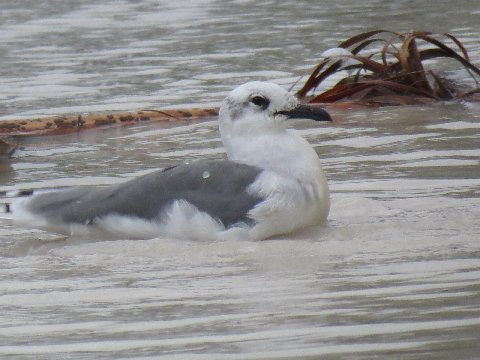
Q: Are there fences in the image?
A: No, there are no fences.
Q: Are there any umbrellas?
A: No, there are no umbrellas.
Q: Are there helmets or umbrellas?
A: No, there are no umbrellas or helmets.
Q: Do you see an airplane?
A: No, there are no airplanes.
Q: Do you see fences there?
A: No, there are no fences.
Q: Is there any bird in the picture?
A: Yes, there is a bird.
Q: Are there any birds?
A: Yes, there is a bird.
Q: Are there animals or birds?
A: Yes, there is a bird.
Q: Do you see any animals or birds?
A: Yes, there is a bird.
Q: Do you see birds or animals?
A: Yes, there is a bird.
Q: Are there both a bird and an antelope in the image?
A: No, there is a bird but no antelopes.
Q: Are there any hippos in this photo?
A: No, there are no hippos.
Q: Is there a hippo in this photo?
A: No, there are no hippos.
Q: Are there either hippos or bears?
A: No, there are no hippos or bears.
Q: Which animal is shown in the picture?
A: The animal is a bird.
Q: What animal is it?
A: The animal is a bird.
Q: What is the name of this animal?
A: That is a bird.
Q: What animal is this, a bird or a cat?
A: That is a bird.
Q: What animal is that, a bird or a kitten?
A: That is a bird.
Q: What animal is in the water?
A: The bird is in the water.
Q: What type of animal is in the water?
A: The animal is a bird.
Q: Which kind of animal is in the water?
A: The animal is a bird.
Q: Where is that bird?
A: The bird is in the water.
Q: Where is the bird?
A: The bird is in the water.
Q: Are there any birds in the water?
A: Yes, there is a bird in the water.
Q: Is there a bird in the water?
A: Yes, there is a bird in the water.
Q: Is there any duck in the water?
A: No, there is a bird in the water.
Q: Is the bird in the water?
A: Yes, the bird is in the water.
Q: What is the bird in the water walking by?
A: The bird is walking by the plants.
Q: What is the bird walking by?
A: The bird is walking by the plants.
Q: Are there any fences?
A: No, there are no fences.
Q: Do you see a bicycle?
A: No, there are no bicycles.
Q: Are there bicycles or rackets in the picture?
A: No, there are no bicycles or rackets.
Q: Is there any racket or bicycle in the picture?
A: No, there are no bicycles or rackets.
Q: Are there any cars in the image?
A: No, there are no cars.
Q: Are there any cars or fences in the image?
A: No, there are no cars or fences.